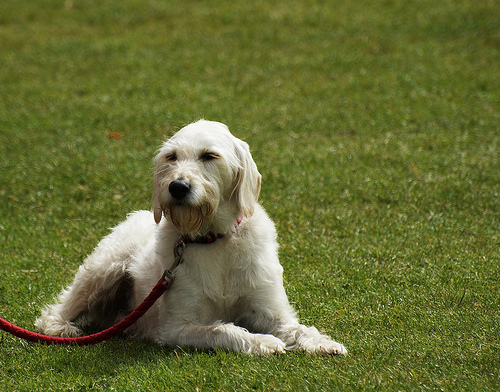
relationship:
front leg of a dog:
[158, 320, 289, 356] [29, 117, 352, 360]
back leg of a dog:
[29, 269, 119, 340] [29, 117, 352, 360]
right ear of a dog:
[148, 145, 167, 223] [29, 117, 352, 360]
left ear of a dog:
[233, 139, 263, 220] [29, 117, 352, 360]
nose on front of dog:
[168, 174, 192, 200] [29, 117, 352, 360]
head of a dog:
[146, 117, 264, 238] [29, 117, 352, 360]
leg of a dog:
[235, 296, 347, 356] [29, 117, 352, 360]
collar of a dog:
[165, 207, 244, 246] [29, 117, 352, 360]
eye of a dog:
[197, 149, 220, 163] [29, 117, 352, 360]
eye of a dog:
[159, 146, 179, 163] [29, 117, 352, 360]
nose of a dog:
[168, 174, 192, 200] [29, 117, 352, 360]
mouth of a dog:
[151, 197, 222, 235] [29, 117, 352, 360]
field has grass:
[0, 0, 498, 392] [0, 0, 499, 392]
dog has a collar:
[29, 117, 352, 360] [165, 207, 244, 246]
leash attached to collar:
[0, 205, 251, 348] [165, 207, 244, 246]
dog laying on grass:
[29, 117, 352, 360] [0, 0, 499, 392]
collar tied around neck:
[165, 207, 244, 246] [162, 204, 249, 245]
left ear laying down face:
[233, 139, 263, 220] [156, 145, 225, 236]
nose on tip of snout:
[168, 174, 192, 200] [166, 160, 199, 201]